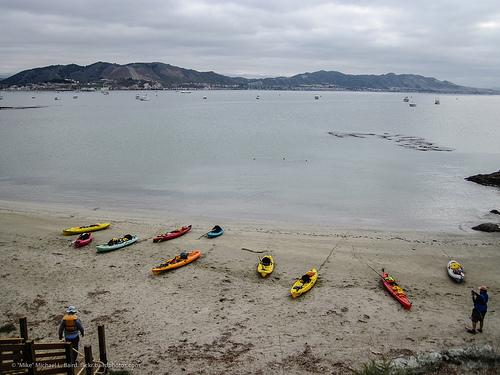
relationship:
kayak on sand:
[288, 267, 324, 300] [2, 203, 500, 374]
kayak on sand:
[151, 223, 193, 244] [2, 203, 500, 374]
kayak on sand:
[150, 249, 203, 275] [2, 203, 500, 374]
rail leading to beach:
[2, 315, 110, 374] [2, 203, 500, 374]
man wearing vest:
[58, 304, 86, 361] [61, 313, 80, 332]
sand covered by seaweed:
[2, 203, 500, 374] [83, 283, 118, 300]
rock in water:
[471, 221, 499, 232] [2, 89, 500, 233]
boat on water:
[409, 101, 419, 109] [2, 89, 500, 233]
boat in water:
[314, 93, 321, 101] [2, 89, 500, 233]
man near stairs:
[58, 304, 86, 361] [41, 350, 125, 375]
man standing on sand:
[58, 304, 86, 361] [2, 203, 500, 374]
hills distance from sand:
[0, 59, 499, 88] [2, 203, 500, 374]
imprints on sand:
[217, 264, 238, 308] [2, 203, 500, 374]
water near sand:
[2, 89, 500, 233] [2, 203, 500, 374]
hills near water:
[0, 59, 499, 88] [2, 89, 500, 233]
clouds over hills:
[0, 1, 499, 78] [0, 59, 499, 88]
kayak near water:
[151, 223, 193, 244] [2, 89, 500, 233]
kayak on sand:
[206, 222, 225, 239] [2, 203, 500, 374]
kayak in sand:
[206, 222, 225, 239] [2, 203, 500, 374]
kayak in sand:
[151, 223, 193, 244] [2, 203, 500, 374]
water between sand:
[2, 89, 500, 233] [2, 203, 500, 374]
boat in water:
[409, 101, 419, 109] [2, 89, 500, 233]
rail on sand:
[2, 315, 110, 374] [2, 203, 500, 374]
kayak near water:
[288, 267, 324, 300] [2, 89, 500, 233]